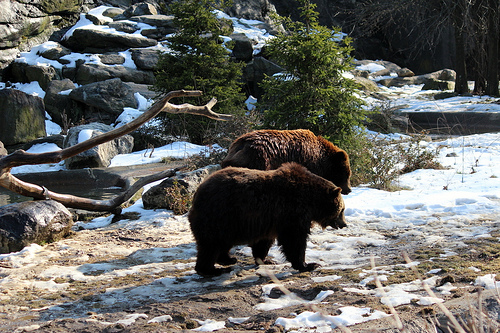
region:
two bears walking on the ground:
[189, 130, 354, 276]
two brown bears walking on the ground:
[189, 131, 354, 276]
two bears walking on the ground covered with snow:
[193, 130, 353, 279]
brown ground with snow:
[346, 176, 485, 298]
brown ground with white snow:
[347, 191, 485, 298]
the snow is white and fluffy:
[389, 178, 477, 220]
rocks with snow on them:
[74, 20, 149, 77]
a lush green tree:
[286, 50, 351, 120]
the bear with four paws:
[189, 235, 344, 275]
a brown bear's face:
[319, 191, 349, 229]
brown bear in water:
[165, 155, 345, 285]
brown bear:
[228, 115, 362, 185]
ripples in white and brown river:
[383, 200, 433, 248]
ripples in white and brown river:
[269, 290, 289, 316]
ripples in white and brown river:
[140, 255, 157, 284]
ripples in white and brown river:
[22, 263, 43, 295]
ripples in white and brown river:
[82, 248, 128, 287]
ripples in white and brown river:
[151, 257, 180, 299]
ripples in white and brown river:
[417, 178, 459, 227]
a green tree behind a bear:
[252, 3, 363, 146]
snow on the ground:
[273, 305, 385, 331]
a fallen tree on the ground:
[2, 85, 235, 212]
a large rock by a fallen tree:
[0, 197, 76, 251]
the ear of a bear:
[330, 184, 342, 197]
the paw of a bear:
[292, 259, 320, 273]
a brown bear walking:
[185, 161, 343, 280]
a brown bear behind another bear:
[227, 126, 349, 199]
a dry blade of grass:
[401, 248, 469, 330]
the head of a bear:
[327, 147, 353, 197]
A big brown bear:
[195, 160, 353, 266]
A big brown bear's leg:
[243, 232, 275, 265]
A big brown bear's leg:
[279, 228, 314, 270]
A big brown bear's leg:
[194, 226, 222, 277]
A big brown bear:
[222, 128, 364, 181]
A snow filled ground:
[397, 160, 495, 210]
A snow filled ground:
[355, 176, 401, 216]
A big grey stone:
[55, 78, 130, 117]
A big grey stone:
[58, 131, 132, 165]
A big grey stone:
[0, 199, 75, 234]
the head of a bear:
[294, 158, 412, 240]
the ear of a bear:
[314, 178, 356, 200]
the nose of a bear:
[326, 210, 353, 236]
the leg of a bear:
[276, 241, 326, 296]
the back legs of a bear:
[168, 171, 259, 285]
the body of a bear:
[164, 145, 350, 292]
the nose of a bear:
[327, 212, 365, 237]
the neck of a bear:
[281, 174, 336, 251]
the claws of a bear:
[293, 248, 342, 283]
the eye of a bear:
[323, 191, 374, 232]